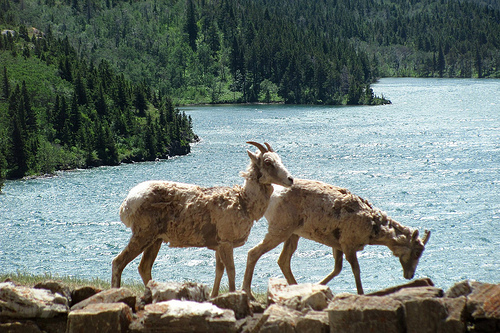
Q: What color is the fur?
A: White.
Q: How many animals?
A: 2.